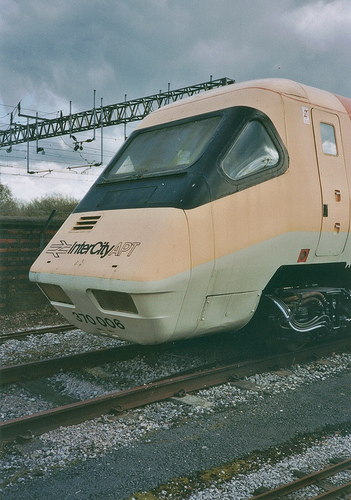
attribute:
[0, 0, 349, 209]
clouds — dark 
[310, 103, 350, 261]
door — white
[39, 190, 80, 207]
leafs — green 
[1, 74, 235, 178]
bridge — metal , wire 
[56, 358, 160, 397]
gravel — light grey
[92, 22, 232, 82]
clouds — large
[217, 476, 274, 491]
rocks — white 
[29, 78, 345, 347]
train — white